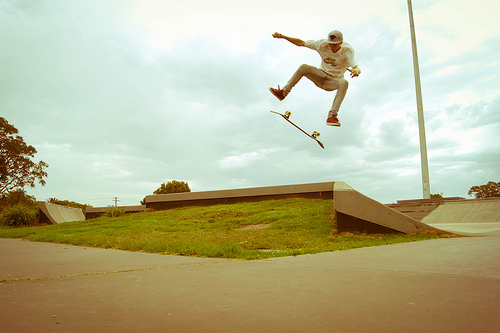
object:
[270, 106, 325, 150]
skateboard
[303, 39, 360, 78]
shirt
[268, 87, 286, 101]
sneaker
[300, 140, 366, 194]
jeans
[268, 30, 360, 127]
man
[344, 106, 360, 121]
hat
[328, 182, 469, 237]
ramp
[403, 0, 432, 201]
pole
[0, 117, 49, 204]
tree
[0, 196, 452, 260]
grass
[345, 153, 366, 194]
leg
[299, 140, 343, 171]
leg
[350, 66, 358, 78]
hand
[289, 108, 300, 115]
hand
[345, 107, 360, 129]
head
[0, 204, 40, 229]
bush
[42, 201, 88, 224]
ramp